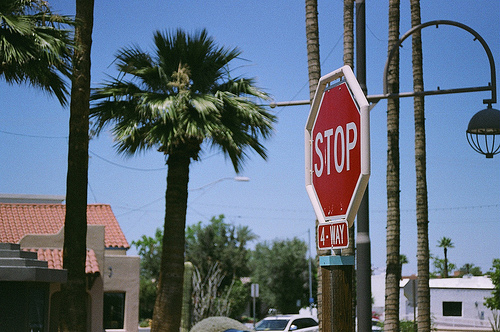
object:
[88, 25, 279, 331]
palm tree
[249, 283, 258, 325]
pole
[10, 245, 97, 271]
roof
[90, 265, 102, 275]
tile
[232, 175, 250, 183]
street light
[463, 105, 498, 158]
street light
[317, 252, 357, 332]
post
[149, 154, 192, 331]
trunk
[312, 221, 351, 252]
sign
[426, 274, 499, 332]
building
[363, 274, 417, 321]
building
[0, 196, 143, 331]
building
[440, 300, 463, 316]
window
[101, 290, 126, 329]
window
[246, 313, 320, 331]
car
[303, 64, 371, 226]
stop sign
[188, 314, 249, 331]
rock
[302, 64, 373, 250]
white border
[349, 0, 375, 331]
pole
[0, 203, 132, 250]
tile roof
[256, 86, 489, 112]
pole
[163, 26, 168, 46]
leaf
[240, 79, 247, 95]
leaf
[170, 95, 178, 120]
leaf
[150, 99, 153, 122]
leaf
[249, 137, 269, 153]
leaf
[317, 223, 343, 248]
4-way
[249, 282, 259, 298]
sign